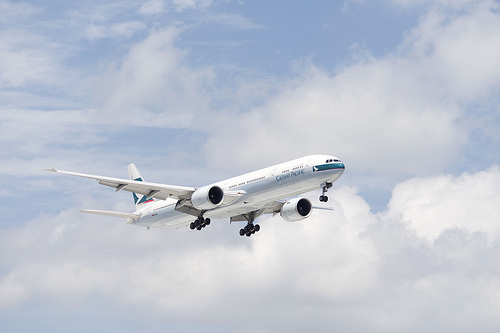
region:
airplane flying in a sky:
[77, 133, 389, 286]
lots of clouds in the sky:
[236, 58, 471, 163]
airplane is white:
[84, 136, 376, 240]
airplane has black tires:
[179, 205, 216, 241]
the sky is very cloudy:
[46, 53, 223, 158]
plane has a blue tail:
[112, 157, 161, 229]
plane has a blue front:
[311, 159, 356, 182]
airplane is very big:
[36, 84, 471, 319]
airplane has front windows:
[323, 154, 343, 162]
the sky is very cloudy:
[213, 43, 338, 90]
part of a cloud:
[313, 230, 350, 269]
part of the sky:
[301, 7, 349, 64]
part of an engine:
[286, 193, 317, 243]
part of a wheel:
[186, 219, 206, 241]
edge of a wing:
[118, 173, 140, 191]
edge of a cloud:
[376, 226, 418, 281]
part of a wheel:
[236, 208, 263, 243]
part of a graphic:
[268, 165, 283, 187]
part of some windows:
[238, 166, 262, 196]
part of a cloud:
[386, 213, 423, 260]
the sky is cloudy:
[336, 244, 362, 282]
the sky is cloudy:
[279, 246, 320, 300]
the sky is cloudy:
[288, 269, 370, 327]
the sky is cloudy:
[347, 271, 384, 314]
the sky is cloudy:
[294, 297, 367, 316]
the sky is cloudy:
[301, 229, 403, 311]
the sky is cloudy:
[367, 251, 404, 308]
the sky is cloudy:
[333, 224, 385, 289]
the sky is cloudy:
[391, 240, 414, 325]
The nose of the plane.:
[328, 158, 352, 180]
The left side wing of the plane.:
[64, 166, 242, 208]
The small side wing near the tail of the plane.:
[84, 200, 152, 222]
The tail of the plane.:
[118, 162, 158, 205]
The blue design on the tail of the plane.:
[127, 171, 148, 203]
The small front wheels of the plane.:
[322, 194, 329, 209]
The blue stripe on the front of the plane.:
[313, 162, 347, 172]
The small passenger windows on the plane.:
[224, 160, 309, 188]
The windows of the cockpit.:
[323, 155, 338, 166]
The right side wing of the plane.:
[276, 192, 333, 216]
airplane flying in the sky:
[40, 140, 361, 242]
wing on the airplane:
[47, 160, 188, 214]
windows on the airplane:
[322, 143, 344, 180]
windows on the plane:
[225, 175, 275, 182]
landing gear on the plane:
[190, 212, 264, 238]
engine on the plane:
[195, 182, 230, 212]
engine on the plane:
[282, 196, 316, 231]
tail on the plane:
[122, 161, 157, 203]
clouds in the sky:
[368, 127, 489, 312]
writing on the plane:
[275, 169, 311, 187]